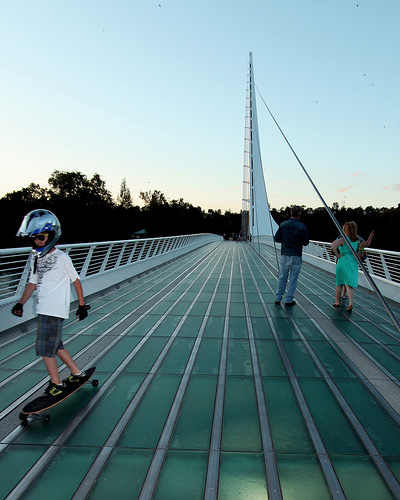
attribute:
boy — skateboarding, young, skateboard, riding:
[11, 201, 93, 398]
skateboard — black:
[20, 362, 102, 428]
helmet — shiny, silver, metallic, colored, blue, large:
[16, 205, 65, 261]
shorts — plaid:
[33, 313, 67, 364]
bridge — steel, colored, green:
[3, 226, 400, 491]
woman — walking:
[328, 219, 367, 317]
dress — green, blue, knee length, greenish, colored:
[336, 233, 363, 288]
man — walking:
[273, 206, 317, 311]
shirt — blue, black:
[276, 218, 315, 257]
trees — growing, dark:
[2, 159, 398, 247]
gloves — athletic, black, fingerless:
[9, 299, 95, 324]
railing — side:
[3, 230, 227, 331]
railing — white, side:
[249, 227, 400, 311]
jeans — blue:
[274, 253, 305, 306]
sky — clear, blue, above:
[3, 0, 398, 254]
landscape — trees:
[3, 160, 400, 248]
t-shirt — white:
[25, 247, 80, 321]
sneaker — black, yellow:
[47, 380, 67, 400]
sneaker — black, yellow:
[69, 370, 85, 386]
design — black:
[32, 253, 62, 305]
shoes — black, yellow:
[270, 297, 298, 311]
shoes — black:
[46, 367, 88, 404]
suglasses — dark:
[30, 235, 49, 244]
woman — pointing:
[335, 219, 376, 257]